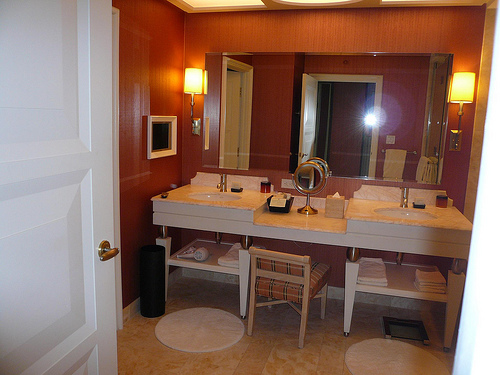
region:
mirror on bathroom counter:
[286, 153, 327, 218]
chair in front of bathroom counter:
[240, 237, 336, 352]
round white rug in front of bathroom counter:
[143, 298, 248, 358]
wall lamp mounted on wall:
[176, 60, 208, 142]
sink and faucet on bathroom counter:
[363, 177, 444, 230]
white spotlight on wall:
[347, 99, 397, 139]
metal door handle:
[83, 221, 123, 268]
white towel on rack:
[375, 143, 422, 185]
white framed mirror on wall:
[136, 101, 188, 166]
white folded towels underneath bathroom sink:
[348, 253, 453, 301]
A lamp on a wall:
[184, 66, 204, 133]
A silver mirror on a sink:
[290, 160, 323, 213]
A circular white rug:
[150, 305, 241, 350]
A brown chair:
[245, 245, 326, 348]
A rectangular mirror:
[201, 50, 452, 185]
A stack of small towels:
[413, 267, 445, 292]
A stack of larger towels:
[353, 255, 384, 285]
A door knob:
[98, 240, 115, 260]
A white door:
[0, 0, 120, 374]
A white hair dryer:
[177, 245, 207, 261]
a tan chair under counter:
[242, 243, 328, 340]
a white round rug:
[148, 306, 245, 353]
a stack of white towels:
[410, 270, 446, 293]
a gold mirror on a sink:
[292, 159, 330, 213]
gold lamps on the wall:
[182, 66, 209, 136]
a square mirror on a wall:
[191, 49, 455, 185]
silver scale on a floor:
[384, 316, 433, 347]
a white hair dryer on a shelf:
[175, 239, 216, 262]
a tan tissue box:
[327, 194, 347, 219]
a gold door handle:
[95, 237, 120, 266]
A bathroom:
[111, 0, 450, 373]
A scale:
[377, 311, 433, 344]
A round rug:
[148, 302, 247, 356]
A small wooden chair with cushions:
[234, 242, 332, 344]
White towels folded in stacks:
[356, 255, 451, 299]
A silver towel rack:
[376, 143, 419, 157]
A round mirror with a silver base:
[289, 157, 329, 216]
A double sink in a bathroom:
[152, 156, 483, 258]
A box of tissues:
[318, 183, 344, 223]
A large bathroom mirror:
[203, 52, 454, 191]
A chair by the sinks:
[245, 244, 330, 346]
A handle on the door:
[97, 244, 117, 259]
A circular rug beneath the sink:
[156, 305, 243, 352]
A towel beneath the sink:
[357, 255, 387, 283]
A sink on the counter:
[375, 184, 438, 221]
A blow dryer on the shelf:
[178, 246, 209, 259]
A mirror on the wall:
[201, 54, 453, 183]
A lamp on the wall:
[448, 71, 475, 148]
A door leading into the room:
[0, 3, 116, 373]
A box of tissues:
[326, 191, 345, 215]